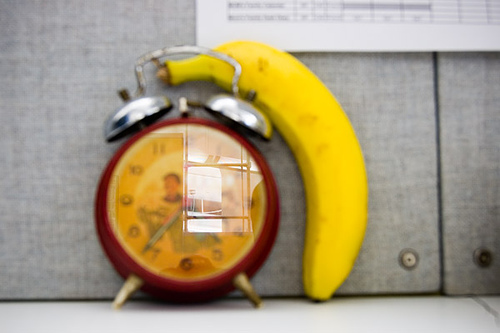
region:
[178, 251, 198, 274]
black number on clock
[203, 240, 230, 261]
black number on clock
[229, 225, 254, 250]
black number on clock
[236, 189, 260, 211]
black number on clock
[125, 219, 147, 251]
black number on clock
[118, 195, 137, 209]
black number on clock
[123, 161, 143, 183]
black number on clock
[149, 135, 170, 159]
black number on clock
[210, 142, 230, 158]
black number on clock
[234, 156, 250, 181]
black number on clock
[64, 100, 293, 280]
round clock in photo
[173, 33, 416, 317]
banana in the photo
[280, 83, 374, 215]
yellow item in photo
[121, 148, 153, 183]
number on the clock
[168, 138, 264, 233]
reflection on the clock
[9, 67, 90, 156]
wall behind the clock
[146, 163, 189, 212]
design on the clock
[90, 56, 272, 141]
silver part of the clock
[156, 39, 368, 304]
A banana is standing up.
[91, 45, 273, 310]
An alarm clock is red.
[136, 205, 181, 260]
A clock hand is on the seven.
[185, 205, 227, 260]
A hand is on a five.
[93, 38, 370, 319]
A banana is next to a clock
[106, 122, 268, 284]
A clock face hasa reflection in it.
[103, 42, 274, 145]
The bells and handle are silver.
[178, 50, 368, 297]
a banana leaning on a wall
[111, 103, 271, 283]
a red alarm clock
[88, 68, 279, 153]
the bells on the alarm clock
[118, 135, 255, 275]
the face of the clock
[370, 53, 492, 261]
a grey wall behind the banana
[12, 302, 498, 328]
a white table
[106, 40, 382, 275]
a banana and an alarm clock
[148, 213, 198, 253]
the minute hand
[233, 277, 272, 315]
the stand of the clock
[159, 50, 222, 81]
the top of the banana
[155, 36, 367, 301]
the banana is yellow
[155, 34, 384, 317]
the banana is yellow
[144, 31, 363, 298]
the banana is yellow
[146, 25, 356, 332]
the banana is yellow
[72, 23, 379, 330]
an alarm clock beside the banana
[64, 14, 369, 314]
an alarm clock beside the banana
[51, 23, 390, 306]
an alarm clock beside the banana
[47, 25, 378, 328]
an alarm clock beside the banana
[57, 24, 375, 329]
an alarm clock beside the banana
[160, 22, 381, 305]
yellow banana beside the clock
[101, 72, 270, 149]
alarm bells on the clock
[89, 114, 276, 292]
red frame of the clock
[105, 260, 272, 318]
feet of the clock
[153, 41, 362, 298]
banana propped on the clock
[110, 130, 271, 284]
yellow face on the clock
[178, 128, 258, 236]
reflection on the clock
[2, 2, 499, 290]
gray wall behind the clock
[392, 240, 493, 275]
bolts in the wall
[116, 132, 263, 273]
black numbers on the clock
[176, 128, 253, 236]
glare on the glass of a clock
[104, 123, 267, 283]
face of a clock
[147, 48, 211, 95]
stem of a banana